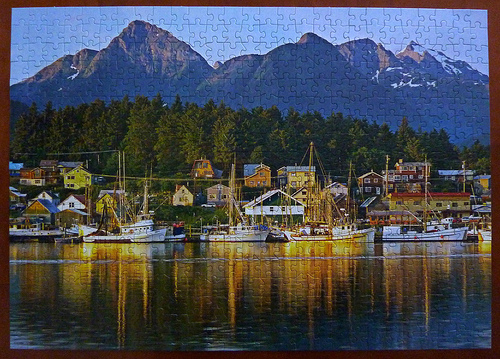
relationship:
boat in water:
[382, 217, 469, 241] [9, 238, 499, 354]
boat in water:
[281, 224, 374, 242] [9, 238, 499, 354]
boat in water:
[200, 223, 271, 242] [9, 238, 499, 354]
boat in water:
[83, 219, 187, 243] [9, 238, 499, 354]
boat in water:
[9, 223, 64, 242] [9, 238, 499, 354]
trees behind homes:
[10, 89, 487, 168] [9, 158, 493, 225]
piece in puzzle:
[415, 22, 443, 44] [7, 9, 494, 354]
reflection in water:
[7, 240, 491, 350] [9, 238, 499, 354]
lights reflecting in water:
[8, 239, 489, 348] [9, 238, 499, 354]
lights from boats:
[8, 239, 489, 348] [10, 149, 490, 241]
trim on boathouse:
[241, 187, 307, 227] [243, 184, 310, 230]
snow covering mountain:
[410, 41, 459, 73] [12, 20, 489, 141]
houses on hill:
[239, 158, 486, 198] [6, 152, 492, 235]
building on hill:
[57, 161, 96, 191] [5, 160, 491, 232]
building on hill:
[15, 160, 56, 189] [5, 160, 491, 232]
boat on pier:
[20, 205, 66, 246] [35, 183, 483, 227]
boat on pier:
[87, 167, 174, 251] [35, 183, 483, 227]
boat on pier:
[201, 160, 271, 243] [35, 183, 483, 227]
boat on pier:
[290, 156, 372, 245] [35, 183, 483, 227]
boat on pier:
[386, 164, 471, 244] [35, 183, 483, 227]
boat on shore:
[382, 217, 469, 241] [139, 190, 381, 259]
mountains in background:
[9, 19, 491, 152] [11, 7, 489, 241]